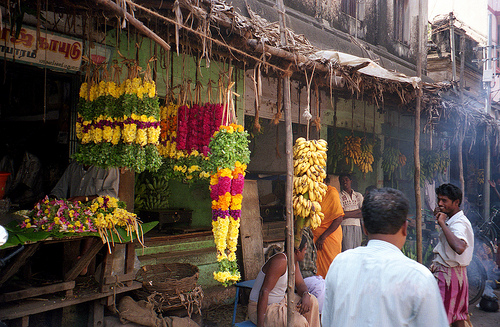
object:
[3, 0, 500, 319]
building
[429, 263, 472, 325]
fabric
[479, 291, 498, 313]
pot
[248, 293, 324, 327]
pants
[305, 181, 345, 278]
vendor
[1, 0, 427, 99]
roof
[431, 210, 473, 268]
shirt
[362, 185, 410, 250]
head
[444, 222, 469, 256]
arms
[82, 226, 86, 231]
flower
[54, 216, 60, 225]
flower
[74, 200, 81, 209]
flower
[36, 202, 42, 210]
flower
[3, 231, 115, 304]
shelf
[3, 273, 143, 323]
counter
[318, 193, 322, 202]
banana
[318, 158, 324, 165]
banana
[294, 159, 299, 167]
banana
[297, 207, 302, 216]
banana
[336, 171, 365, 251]
person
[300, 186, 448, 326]
person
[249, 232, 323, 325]
person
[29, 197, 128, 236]
food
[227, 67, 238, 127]
rope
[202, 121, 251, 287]
food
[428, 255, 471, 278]
waist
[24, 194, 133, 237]
bouquet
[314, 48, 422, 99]
awning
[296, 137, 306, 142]
banana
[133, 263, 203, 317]
basket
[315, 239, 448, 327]
shirt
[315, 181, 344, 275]
dress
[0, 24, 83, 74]
sign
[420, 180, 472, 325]
man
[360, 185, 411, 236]
hair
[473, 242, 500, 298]
smoke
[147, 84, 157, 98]
flower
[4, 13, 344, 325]
shop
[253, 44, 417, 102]
supporter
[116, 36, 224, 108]
wall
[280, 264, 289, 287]
chest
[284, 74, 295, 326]
pole